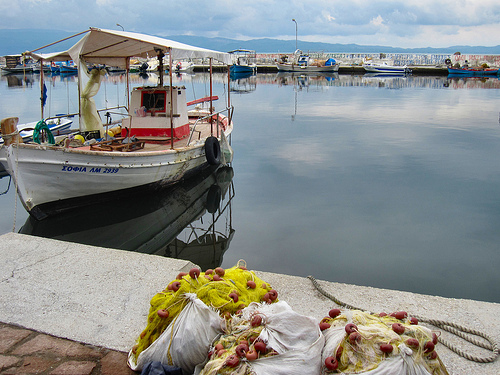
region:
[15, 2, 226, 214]
white boat in river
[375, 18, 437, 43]
white snow on hill side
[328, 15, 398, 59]
white snow on hill side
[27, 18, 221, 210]
white boat in river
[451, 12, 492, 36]
white clouds in blue sky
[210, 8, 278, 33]
white clouds in blue sky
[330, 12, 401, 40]
white clouds in blue sky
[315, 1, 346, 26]
white clouds in blue sky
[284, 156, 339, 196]
calm dark blue water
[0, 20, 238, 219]
fishing boat is white and pink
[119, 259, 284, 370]
fishing net is yellow with red balls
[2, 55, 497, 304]
harbor water is very calm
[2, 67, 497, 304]
water is very reflective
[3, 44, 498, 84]
boats in the background sitting in the harbor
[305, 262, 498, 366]
a sturdy thick rope next to the fishing nets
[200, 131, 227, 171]
a black tire hanging off the boat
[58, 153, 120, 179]
name of the boat written in blue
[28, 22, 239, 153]
a roof on top of the boat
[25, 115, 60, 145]
a green rope on the boat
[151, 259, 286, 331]
fishing net is yellow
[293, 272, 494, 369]
rope is hanging from the dock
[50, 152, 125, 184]
boat has blue writing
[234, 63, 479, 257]
water is very still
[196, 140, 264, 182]
boat has tire on the side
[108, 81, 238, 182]
boat has red trim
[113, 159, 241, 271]
reflection of the boat in the water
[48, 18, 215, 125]
boat has a white tent cover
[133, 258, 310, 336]
yellow net on sidewalk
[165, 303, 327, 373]
white net on sidewalk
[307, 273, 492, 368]
tan rope on sidewalk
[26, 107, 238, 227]
white boat in water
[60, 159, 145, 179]
blue name on boat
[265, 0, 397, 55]
white and blue sky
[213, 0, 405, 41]
large clouds in sky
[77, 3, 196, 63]
white roof on boat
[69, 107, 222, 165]
brown deck on boat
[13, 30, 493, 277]
a scene at a harbor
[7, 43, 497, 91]
a row of boats in the background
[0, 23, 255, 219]
a white boat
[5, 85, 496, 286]
a body of water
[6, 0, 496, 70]
a sky with clouds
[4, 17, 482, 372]
a scene outside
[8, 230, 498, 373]
a gray pavement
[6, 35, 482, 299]
a scene of boats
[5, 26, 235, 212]
boat on the water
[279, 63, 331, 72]
the shoe is white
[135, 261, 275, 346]
the net is yellow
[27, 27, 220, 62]
the canopy is white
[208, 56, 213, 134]
the pole is brown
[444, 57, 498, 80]
A boat on the water.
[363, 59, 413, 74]
A boat on the water.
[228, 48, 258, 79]
A boat on the water.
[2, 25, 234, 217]
A boat on the water.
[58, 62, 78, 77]
A boat on the water.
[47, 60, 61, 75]
A boat on the water.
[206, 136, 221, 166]
A vehicle's tire attached to a boat